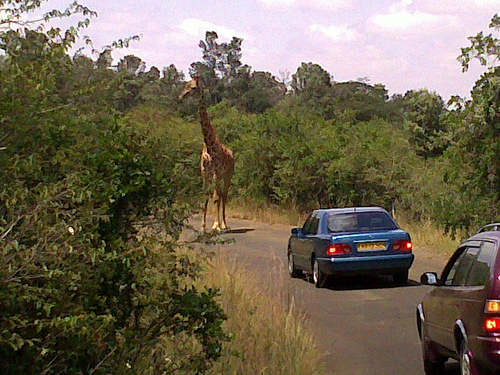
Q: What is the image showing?
A: It is showing a path.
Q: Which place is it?
A: It is a path.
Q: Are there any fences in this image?
A: No, there are no fences.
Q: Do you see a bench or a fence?
A: No, there are no fences or benches.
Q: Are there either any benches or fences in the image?
A: No, there are no fences or benches.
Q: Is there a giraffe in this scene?
A: Yes, there is a giraffe.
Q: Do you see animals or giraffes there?
A: Yes, there is a giraffe.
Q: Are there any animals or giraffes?
A: Yes, there is a giraffe.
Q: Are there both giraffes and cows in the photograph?
A: No, there is a giraffe but no cows.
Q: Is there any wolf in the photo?
A: No, there are no wolves.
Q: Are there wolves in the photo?
A: No, there are no wolves.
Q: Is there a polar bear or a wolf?
A: No, there are no wolves or polar bears.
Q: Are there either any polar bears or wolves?
A: No, there are no wolves or polar bears.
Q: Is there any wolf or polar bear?
A: No, there are no wolves or polar bears.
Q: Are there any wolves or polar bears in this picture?
A: No, there are no wolves or polar bears.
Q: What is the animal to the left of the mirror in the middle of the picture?
A: The animal is a giraffe.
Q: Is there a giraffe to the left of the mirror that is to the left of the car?
A: Yes, there is a giraffe to the left of the mirror.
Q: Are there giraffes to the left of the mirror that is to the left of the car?
A: Yes, there is a giraffe to the left of the mirror.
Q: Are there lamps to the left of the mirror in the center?
A: No, there is a giraffe to the left of the mirror.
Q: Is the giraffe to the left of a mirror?
A: Yes, the giraffe is to the left of a mirror.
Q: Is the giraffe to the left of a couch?
A: No, the giraffe is to the left of a mirror.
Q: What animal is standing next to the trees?
A: The giraffe is standing next to the trees.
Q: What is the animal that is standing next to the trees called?
A: The animal is a giraffe.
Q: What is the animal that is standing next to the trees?
A: The animal is a giraffe.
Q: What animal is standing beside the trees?
A: The animal is a giraffe.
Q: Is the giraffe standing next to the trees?
A: Yes, the giraffe is standing next to the trees.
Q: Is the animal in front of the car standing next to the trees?
A: Yes, the giraffe is standing next to the trees.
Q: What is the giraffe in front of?
A: The giraffe is in front of the car.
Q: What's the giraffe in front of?
A: The giraffe is in front of the car.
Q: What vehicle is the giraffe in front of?
A: The giraffe is in front of the car.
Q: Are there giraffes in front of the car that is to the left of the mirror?
A: Yes, there is a giraffe in front of the car.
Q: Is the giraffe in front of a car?
A: Yes, the giraffe is in front of a car.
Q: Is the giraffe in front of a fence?
A: No, the giraffe is in front of a car.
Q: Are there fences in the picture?
A: No, there are no fences.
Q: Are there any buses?
A: No, there are no buses.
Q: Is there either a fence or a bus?
A: No, there are no buses or fences.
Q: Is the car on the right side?
A: Yes, the car is on the right of the image.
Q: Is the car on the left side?
A: No, the car is on the right of the image.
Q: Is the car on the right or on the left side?
A: The car is on the right of the image.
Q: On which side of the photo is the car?
A: The car is on the right of the image.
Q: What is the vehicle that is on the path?
A: The vehicle is a car.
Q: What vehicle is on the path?
A: The vehicle is a car.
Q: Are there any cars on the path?
A: Yes, there is a car on the path.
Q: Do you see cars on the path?
A: Yes, there is a car on the path.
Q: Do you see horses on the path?
A: No, there is a car on the path.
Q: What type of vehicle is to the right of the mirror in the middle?
A: The vehicle is a car.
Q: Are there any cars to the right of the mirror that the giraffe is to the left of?
A: Yes, there is a car to the right of the mirror.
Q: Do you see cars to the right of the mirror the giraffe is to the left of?
A: Yes, there is a car to the right of the mirror.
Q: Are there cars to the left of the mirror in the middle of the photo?
A: No, the car is to the right of the mirror.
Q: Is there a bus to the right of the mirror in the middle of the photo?
A: No, there is a car to the right of the mirror.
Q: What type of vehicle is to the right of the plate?
A: The vehicle is a car.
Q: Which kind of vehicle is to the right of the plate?
A: The vehicle is a car.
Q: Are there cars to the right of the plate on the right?
A: Yes, there is a car to the right of the plate.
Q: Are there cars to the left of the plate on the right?
A: No, the car is to the right of the plate.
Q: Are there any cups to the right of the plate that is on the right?
A: No, there is a car to the right of the plate.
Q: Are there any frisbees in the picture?
A: No, there are no frisbees.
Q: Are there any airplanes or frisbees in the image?
A: No, there are no frisbees or airplanes.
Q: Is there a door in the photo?
A: Yes, there is a door.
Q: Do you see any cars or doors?
A: Yes, there is a door.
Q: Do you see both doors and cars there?
A: Yes, there are both a door and a car.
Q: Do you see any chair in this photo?
A: No, there are no chairs.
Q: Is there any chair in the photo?
A: No, there are no chairs.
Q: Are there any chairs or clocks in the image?
A: No, there are no chairs or clocks.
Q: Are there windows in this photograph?
A: Yes, there is a window.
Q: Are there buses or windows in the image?
A: Yes, there is a window.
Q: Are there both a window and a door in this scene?
A: Yes, there are both a window and a door.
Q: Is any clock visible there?
A: No, there are no clocks.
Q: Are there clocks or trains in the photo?
A: No, there are no clocks or trains.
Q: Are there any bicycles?
A: No, there are no bicycles.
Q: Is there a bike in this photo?
A: No, there are no bikes.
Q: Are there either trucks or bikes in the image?
A: No, there are no bikes or trucks.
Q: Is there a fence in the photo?
A: No, there are no fences.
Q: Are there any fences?
A: No, there are no fences.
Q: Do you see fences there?
A: No, there are no fences.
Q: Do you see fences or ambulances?
A: No, there are no fences or ambulances.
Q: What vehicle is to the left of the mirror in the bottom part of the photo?
A: The vehicle is a car.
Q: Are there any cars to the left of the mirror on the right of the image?
A: Yes, there is a car to the left of the mirror.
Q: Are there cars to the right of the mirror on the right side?
A: No, the car is to the left of the mirror.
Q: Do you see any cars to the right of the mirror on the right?
A: No, the car is to the left of the mirror.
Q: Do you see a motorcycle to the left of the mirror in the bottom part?
A: No, there is a car to the left of the mirror.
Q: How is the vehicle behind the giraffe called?
A: The vehicle is a car.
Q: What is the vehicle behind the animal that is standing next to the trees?
A: The vehicle is a car.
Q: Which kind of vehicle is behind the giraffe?
A: The vehicle is a car.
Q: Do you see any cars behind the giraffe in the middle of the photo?
A: Yes, there is a car behind the giraffe.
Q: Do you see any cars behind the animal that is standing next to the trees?
A: Yes, there is a car behind the giraffe.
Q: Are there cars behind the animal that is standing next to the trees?
A: Yes, there is a car behind the giraffe.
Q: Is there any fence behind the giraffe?
A: No, there is a car behind the giraffe.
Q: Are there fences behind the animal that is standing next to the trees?
A: No, there is a car behind the giraffe.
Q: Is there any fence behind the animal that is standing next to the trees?
A: No, there is a car behind the giraffe.